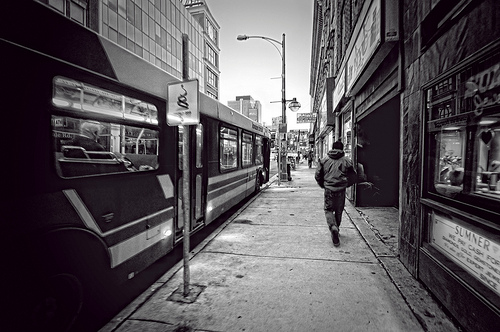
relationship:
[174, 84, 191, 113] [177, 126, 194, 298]
sign on pole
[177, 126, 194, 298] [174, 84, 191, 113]
pole with a sign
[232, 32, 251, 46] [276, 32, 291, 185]
light on pole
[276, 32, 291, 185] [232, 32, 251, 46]
pole with light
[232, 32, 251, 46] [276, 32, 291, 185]
light with pole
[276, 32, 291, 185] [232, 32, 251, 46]
pole has light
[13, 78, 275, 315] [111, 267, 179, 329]
bus at curb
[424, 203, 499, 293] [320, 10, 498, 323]
sign on building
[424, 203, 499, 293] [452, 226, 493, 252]
sign reads sumner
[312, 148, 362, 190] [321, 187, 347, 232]
jacket and pants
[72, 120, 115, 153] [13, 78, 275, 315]
person on bus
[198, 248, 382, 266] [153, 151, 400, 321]
lines are on sidewalk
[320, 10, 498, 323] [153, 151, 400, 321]
building behind sidewalk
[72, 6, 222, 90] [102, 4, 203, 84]
building covered with panels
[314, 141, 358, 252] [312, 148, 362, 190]
person in jacket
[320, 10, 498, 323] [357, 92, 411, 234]
building has entryway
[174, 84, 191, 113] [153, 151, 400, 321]
sign on sidewalk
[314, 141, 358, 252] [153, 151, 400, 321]
person walking down sidewalk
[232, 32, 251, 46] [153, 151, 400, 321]
light on sidewalk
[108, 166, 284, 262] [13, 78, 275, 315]
lines are on bus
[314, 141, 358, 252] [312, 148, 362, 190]
person wearing jacket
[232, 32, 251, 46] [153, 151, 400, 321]
light over sidewalk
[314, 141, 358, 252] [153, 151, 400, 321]
person on sidewalk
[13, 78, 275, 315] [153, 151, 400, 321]
bus parked by sidewalk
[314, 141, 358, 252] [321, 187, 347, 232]
person wears pants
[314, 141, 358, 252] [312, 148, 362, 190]
person wears jacket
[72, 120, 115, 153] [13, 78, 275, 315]
person inside bus